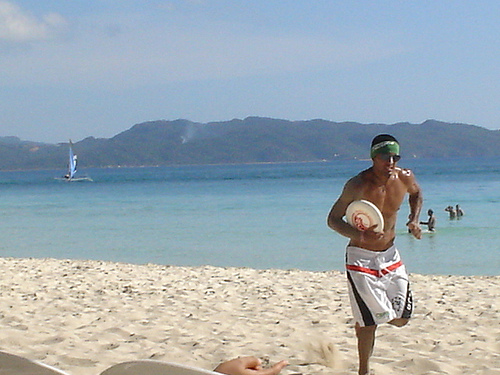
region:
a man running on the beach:
[337, 126, 441, 368]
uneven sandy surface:
[82, 270, 221, 336]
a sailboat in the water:
[50, 137, 105, 192]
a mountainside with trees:
[107, 107, 336, 182]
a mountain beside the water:
[108, 118, 308, 190]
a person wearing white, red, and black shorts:
[329, 233, 423, 327]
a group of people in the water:
[415, 190, 481, 236]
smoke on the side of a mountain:
[168, 115, 215, 157]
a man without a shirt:
[323, 138, 442, 244]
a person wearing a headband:
[367, 131, 402, 161]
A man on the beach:
[348, 128, 445, 346]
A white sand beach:
[228, 265, 330, 323]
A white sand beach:
[422, 280, 492, 365]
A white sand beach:
[130, 254, 244, 356]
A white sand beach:
[20, 260, 127, 368]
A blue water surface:
[34, 201, 199, 263]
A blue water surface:
[208, 200, 329, 280]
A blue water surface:
[104, 155, 214, 187]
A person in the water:
[443, 185, 466, 232]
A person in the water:
[410, 200, 440, 237]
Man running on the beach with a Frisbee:
[327, 132, 426, 374]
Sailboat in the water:
[51, 140, 93, 189]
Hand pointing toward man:
[213, 348, 295, 373]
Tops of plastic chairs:
[0, 351, 215, 374]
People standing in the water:
[422, 197, 465, 234]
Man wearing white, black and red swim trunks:
[323, 142, 422, 374]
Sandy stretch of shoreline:
[1, 255, 497, 372]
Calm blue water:
[0, 172, 498, 270]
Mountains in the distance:
[0, 116, 498, 176]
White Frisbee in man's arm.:
[340, 197, 386, 233]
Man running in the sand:
[325, 134, 425, 373]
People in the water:
[418, 198, 467, 233]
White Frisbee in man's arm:
[345, 198, 386, 238]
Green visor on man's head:
[371, 137, 401, 157]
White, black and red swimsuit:
[343, 243, 413, 329]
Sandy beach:
[0, 256, 496, 372]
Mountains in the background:
[0, 115, 499, 177]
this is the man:
[328, 128, 425, 372]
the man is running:
[334, 130, 431, 373]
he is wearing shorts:
[347, 245, 406, 315]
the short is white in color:
[343, 250, 390, 285]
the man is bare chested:
[370, 170, 409, 193]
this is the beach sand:
[124, 260, 236, 335]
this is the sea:
[173, 164, 285, 258]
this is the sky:
[290, 20, 400, 89]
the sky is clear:
[260, 7, 408, 81]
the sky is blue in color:
[269, 15, 384, 77]